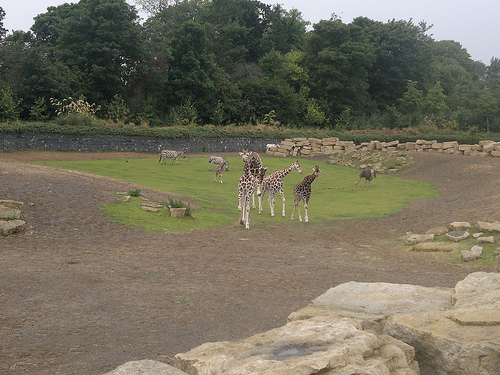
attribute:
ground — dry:
[230, 259, 297, 307]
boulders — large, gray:
[281, 134, 397, 169]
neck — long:
[276, 165, 290, 178]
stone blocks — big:
[357, 132, 454, 170]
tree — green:
[27, 0, 145, 128]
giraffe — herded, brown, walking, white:
[237, 165, 268, 229]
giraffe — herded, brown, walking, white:
[259, 160, 303, 217]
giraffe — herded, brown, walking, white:
[291, 165, 323, 222]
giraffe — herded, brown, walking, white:
[241, 147, 263, 170]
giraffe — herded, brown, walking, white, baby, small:
[214, 159, 229, 183]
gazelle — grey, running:
[355, 165, 378, 188]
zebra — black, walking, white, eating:
[157, 149, 186, 165]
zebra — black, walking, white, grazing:
[208, 155, 231, 172]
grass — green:
[29, 153, 436, 238]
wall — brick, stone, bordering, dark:
[1, 130, 284, 153]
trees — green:
[0, 0, 499, 136]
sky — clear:
[1, 0, 499, 68]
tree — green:
[137, 0, 308, 126]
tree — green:
[306, 11, 436, 125]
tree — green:
[428, 36, 498, 131]